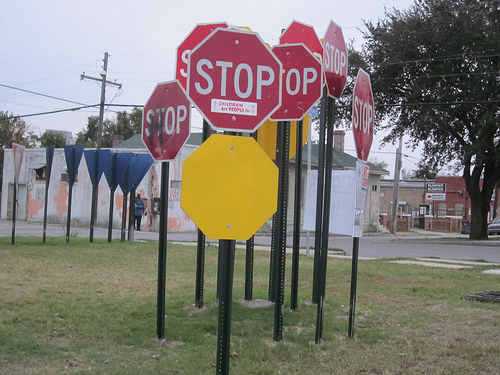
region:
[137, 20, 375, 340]
group of stop signs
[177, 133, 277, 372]
Octagonal yellow sign in the front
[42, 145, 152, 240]
group of blue signs to the left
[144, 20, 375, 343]
seven stop signs grouped together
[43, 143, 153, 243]
seven blue signs to the left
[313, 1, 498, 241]
large tree on the right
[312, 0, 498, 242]
large, green tree in the distance to the right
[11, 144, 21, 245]
white sign in front of blue signs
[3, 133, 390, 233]
white buildings in the back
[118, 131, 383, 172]
gray roof of house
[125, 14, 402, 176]
seven stop sign clustered together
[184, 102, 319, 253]
two yellow octagon shaped signs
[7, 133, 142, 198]
seven yield signs clustered together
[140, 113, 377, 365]
green posts holding up stop signs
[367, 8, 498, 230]
tree on right side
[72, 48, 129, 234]
power line pole behind yield signs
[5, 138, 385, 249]
white building behind signs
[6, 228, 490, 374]
patch of grass signs are on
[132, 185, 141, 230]
person standing across street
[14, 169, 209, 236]
pink splotches on white building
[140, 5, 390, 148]
This are stop signs.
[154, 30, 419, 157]
This sign is yellow.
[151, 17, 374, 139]
The signs are red.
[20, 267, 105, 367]
This grass is brown and green.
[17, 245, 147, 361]
This lawn is mad of grass.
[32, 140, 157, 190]
These are yield signs.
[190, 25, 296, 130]
The sign is shaped like an octogon.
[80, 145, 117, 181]
This sign is shaped like a triangle.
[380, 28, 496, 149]
The tree is dark green.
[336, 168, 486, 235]
This is a public street.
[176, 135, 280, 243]
a yellow hexagon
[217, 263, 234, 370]
a black pole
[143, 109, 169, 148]
tagging on the stop sign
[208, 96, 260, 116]
a sticker on the stop sign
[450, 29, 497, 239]
a green tree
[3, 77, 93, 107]
an electrical line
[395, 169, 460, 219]
a building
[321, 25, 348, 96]
the stop sign is red and white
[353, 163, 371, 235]
a poster on the stop sign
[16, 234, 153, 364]
the green grass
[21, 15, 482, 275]
multiple stop signs on the grass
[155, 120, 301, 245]
an incomplete stop sign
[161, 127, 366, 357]
green poles on the stop signs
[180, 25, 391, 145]
these are extra stop signs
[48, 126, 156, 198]
the back part of some street signs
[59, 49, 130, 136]
a utility pole in the shot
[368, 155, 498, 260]
buildings on the street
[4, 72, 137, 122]
wires on over the street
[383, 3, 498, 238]
a big tree in the area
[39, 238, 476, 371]
sparsely covered grass